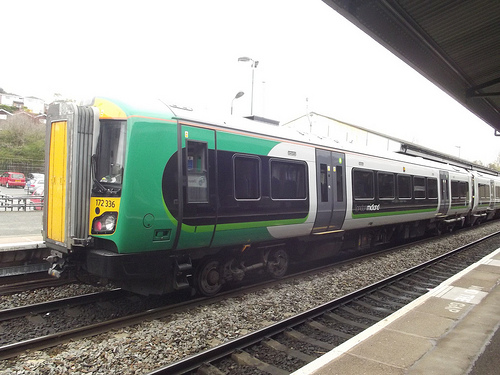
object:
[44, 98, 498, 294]
train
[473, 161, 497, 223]
last car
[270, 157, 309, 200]
windows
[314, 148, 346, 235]
doors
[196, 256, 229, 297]
wheels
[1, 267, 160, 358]
rails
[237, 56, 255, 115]
lamp post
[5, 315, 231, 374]
gravel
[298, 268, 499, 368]
loading ramp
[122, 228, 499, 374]
second rails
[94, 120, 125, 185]
windows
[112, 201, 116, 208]
numbers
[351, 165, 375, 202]
windows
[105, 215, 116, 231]
headlight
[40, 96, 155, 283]
train front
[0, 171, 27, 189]
cars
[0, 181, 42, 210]
parking lot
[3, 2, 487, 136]
sky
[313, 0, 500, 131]
roof